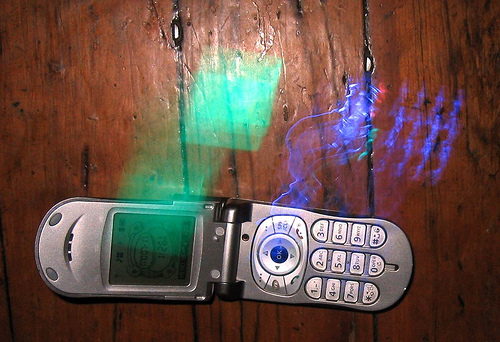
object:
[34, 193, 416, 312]
cellphone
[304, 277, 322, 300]
number button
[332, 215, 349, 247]
number button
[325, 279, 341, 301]
number button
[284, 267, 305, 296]
answer button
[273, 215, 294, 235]
button light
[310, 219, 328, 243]
button light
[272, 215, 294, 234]
button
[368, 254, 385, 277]
button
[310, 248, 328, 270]
button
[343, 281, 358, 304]
button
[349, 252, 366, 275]
button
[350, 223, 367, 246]
button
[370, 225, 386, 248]
button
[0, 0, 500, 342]
table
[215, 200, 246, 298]
hinge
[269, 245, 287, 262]
cellphone button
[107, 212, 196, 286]
cellphone screen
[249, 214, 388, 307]
cellphone bottom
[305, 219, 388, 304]
cellphone numbers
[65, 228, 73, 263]
speaker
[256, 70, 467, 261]
blur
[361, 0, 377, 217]
crack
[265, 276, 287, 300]
phone buttons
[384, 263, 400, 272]
phone speaker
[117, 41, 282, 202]
green reflection